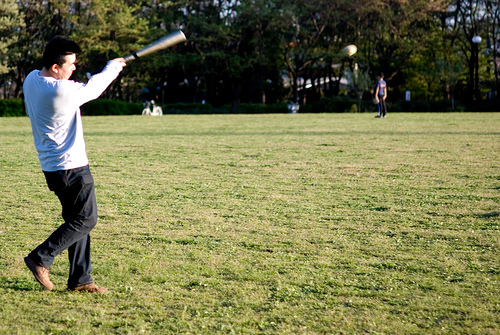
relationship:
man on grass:
[16, 35, 133, 302] [218, 149, 488, 315]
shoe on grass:
[69, 282, 106, 294] [201, 122, 461, 301]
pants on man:
[31, 170, 124, 281] [22, 40, 119, 290]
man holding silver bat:
[22, 35, 127, 294] [123, 30, 185, 65]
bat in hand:
[115, 25, 191, 60] [107, 52, 127, 71]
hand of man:
[107, 52, 127, 71] [22, 35, 127, 294]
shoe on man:
[23, 252, 54, 291] [22, 35, 127, 294]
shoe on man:
[69, 282, 106, 294] [22, 35, 127, 294]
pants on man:
[24, 161, 96, 282] [17, 25, 176, 309]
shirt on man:
[19, 55, 144, 179] [7, 17, 134, 321]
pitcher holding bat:
[373, 72, 388, 116] [100, 9, 212, 71]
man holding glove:
[373, 73, 384, 115] [370, 89, 391, 111]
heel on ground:
[20, 255, 33, 267] [1, 112, 498, 332]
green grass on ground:
[1, 111, 498, 333] [1, 112, 498, 332]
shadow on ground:
[467, 208, 497, 220] [1, 112, 498, 332]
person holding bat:
[13, 33, 131, 298] [104, 15, 189, 80]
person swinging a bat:
[13, 33, 159, 314] [107, 23, 202, 74]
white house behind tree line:
[284, 59, 358, 111] [0, 6, 498, 113]